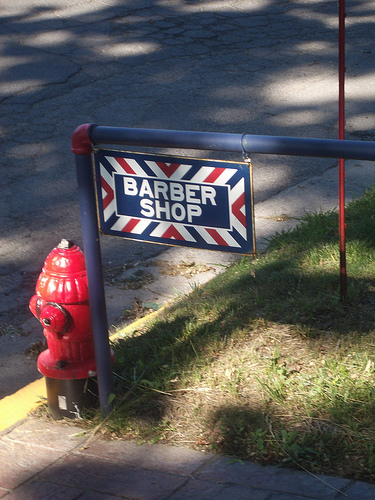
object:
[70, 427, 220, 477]
brick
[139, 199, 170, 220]
sh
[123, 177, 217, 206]
barber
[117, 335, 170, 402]
part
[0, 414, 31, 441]
edge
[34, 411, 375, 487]
edge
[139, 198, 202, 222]
shop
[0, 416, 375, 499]
floor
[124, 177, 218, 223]
"barber shop"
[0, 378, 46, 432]
yellow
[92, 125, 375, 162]
railing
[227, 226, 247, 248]
line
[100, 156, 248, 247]
background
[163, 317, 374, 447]
light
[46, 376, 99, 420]
bottom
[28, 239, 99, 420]
fire hydrant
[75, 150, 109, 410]
pole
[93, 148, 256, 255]
sign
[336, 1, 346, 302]
pole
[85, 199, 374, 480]
grass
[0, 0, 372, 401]
road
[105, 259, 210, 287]
trash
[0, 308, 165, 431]
curb